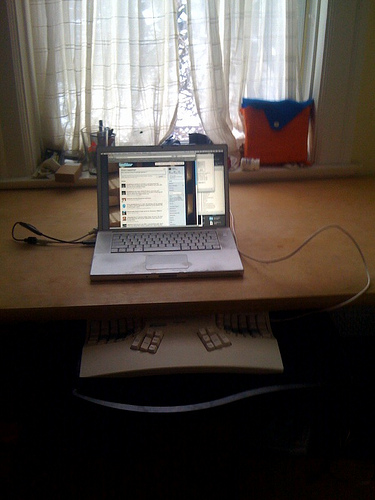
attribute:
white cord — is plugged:
[262, 237, 323, 309]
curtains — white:
[10, 1, 328, 166]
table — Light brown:
[0, 170, 373, 310]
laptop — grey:
[92, 151, 255, 217]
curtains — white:
[36, 2, 318, 155]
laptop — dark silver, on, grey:
[87, 140, 247, 283]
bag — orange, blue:
[239, 96, 314, 166]